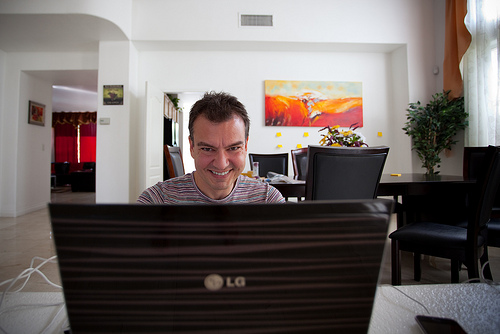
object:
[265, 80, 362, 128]
painting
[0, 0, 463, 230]
wall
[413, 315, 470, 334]
phone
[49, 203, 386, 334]
laptop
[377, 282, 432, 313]
cable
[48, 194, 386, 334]
screen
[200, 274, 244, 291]
logo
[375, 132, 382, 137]
sticker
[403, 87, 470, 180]
plant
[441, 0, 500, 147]
curtain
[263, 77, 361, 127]
picture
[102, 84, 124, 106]
picture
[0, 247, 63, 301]
cables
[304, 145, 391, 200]
chair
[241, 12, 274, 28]
vent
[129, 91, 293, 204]
man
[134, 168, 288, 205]
shirt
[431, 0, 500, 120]
curatins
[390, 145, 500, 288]
black chair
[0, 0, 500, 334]
table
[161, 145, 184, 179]
chair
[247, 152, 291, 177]
chair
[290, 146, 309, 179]
chair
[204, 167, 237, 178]
smiling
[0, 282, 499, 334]
desk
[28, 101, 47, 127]
picture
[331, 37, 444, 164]
corner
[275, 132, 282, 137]
sticker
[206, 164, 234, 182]
man smiling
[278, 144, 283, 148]
sticker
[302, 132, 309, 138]
sticker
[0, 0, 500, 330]
room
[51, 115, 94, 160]
curtain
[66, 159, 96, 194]
chair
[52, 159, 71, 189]
chair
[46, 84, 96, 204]
room